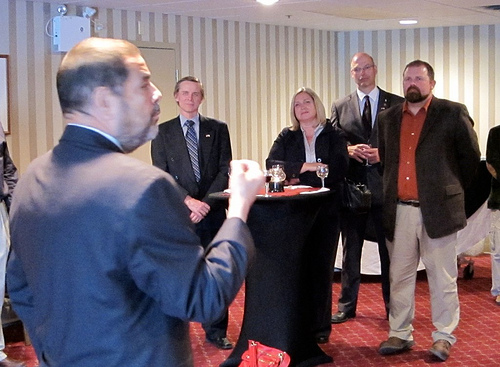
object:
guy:
[377, 59, 481, 361]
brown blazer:
[377, 97, 482, 243]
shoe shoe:
[377, 337, 451, 361]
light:
[399, 19, 417, 24]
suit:
[5, 121, 258, 367]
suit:
[151, 112, 232, 340]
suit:
[330, 85, 405, 314]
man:
[330, 52, 406, 324]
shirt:
[355, 86, 379, 129]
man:
[3, 37, 264, 367]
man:
[150, 76, 233, 349]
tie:
[361, 96, 373, 139]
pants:
[337, 209, 390, 314]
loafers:
[378, 337, 414, 355]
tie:
[184, 120, 200, 182]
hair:
[56, 37, 139, 113]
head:
[56, 37, 162, 153]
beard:
[406, 86, 429, 103]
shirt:
[397, 99, 433, 202]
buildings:
[0, 0, 500, 281]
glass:
[316, 165, 330, 191]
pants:
[387, 204, 460, 345]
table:
[208, 184, 344, 366]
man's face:
[125, 53, 163, 138]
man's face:
[178, 81, 202, 112]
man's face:
[351, 55, 374, 87]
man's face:
[403, 64, 431, 101]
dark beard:
[114, 98, 161, 152]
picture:
[0, 57, 7, 134]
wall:
[2, 1, 340, 177]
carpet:
[2, 249, 497, 364]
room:
[0, 0, 500, 365]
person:
[265, 87, 352, 343]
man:
[485, 125, 499, 304]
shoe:
[430, 339, 451, 361]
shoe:
[378, 336, 414, 354]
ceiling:
[4, 0, 500, 33]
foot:
[378, 337, 416, 355]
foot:
[429, 339, 452, 360]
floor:
[0, 256, 500, 367]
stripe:
[175, 14, 212, 82]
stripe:
[226, 18, 235, 92]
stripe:
[277, 32, 306, 86]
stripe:
[453, 29, 473, 98]